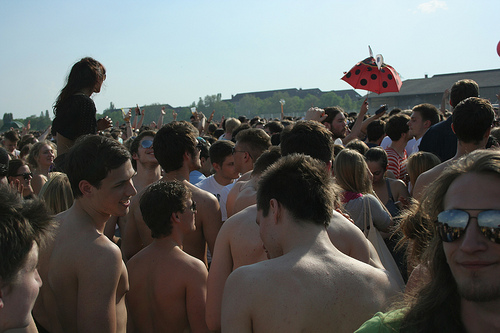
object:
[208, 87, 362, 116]
buildings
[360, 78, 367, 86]
polka dots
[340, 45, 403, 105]
umbrella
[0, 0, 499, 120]
sky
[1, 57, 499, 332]
people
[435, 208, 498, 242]
sunglasses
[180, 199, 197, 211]
sunglasses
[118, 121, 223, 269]
man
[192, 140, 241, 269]
man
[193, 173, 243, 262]
shirt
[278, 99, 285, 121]
road sign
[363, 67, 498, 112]
house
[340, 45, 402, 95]
umbrella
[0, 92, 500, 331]
crowd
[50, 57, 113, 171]
person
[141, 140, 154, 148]
sun glasses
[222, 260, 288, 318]
shoulder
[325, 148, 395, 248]
woman's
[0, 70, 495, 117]
background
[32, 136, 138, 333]
guy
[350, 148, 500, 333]
man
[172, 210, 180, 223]
ear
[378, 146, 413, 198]
shirt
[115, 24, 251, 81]
sky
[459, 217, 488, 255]
nose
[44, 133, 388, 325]
men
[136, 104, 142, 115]
bottle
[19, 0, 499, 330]
air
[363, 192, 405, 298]
bag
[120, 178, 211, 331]
man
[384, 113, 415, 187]
person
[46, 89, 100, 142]
shirt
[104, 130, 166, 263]
man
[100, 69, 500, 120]
buildings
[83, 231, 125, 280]
shoulders